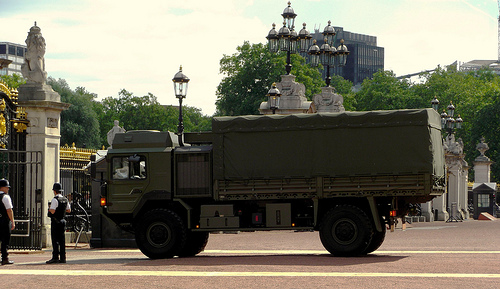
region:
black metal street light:
[168, 65, 195, 99]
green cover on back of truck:
[215, 104, 441, 177]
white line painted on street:
[236, 255, 376, 287]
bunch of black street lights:
[260, 7, 352, 70]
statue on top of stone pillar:
[20, 22, 69, 102]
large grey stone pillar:
[25, 106, 59, 182]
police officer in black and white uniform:
[43, 179, 79, 271]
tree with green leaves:
[353, 71, 412, 107]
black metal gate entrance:
[13, 148, 43, 254]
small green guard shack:
[469, 177, 497, 222]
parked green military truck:
[84, 105, 456, 267]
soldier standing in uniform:
[38, 175, 73, 273]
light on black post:
[168, 62, 190, 109]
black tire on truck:
[309, 192, 378, 259]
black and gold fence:
[62, 139, 92, 194]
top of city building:
[345, 30, 391, 70]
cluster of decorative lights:
[261, 5, 313, 67]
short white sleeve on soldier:
[2, 190, 22, 218]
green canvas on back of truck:
[204, 117, 448, 187]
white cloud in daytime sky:
[402, 12, 482, 61]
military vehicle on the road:
[12, 25, 482, 279]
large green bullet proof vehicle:
[80, 87, 452, 281]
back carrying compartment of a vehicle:
[190, 98, 482, 209]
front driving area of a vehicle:
[80, 122, 194, 263]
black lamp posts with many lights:
[255, 8, 367, 89]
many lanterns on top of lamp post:
[242, 18, 369, 85]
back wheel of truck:
[317, 192, 385, 264]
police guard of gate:
[0, 171, 127, 261]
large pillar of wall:
[20, 65, 70, 246]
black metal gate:
[4, 144, 68, 272]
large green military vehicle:
[22, 18, 496, 259]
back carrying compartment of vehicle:
[194, 107, 478, 231]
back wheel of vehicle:
[295, 187, 375, 268]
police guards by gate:
[5, 155, 103, 256]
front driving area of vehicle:
[92, 115, 177, 279]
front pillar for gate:
[40, 24, 65, 282]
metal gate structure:
[5, 120, 65, 267]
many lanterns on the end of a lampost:
[220, 12, 361, 62]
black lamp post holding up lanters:
[261, 42, 346, 117]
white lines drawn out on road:
[28, 250, 470, 287]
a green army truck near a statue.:
[75, 51, 475, 266]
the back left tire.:
[312, 169, 407, 267]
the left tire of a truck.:
[130, 181, 217, 270]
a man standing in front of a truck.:
[43, 170, 82, 255]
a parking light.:
[163, 55, 202, 150]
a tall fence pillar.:
[0, 26, 65, 244]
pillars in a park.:
[0, 19, 495, 246]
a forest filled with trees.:
[215, 28, 395, 118]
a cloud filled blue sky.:
[0, 0, 496, 112]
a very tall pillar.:
[238, 70, 350, 118]